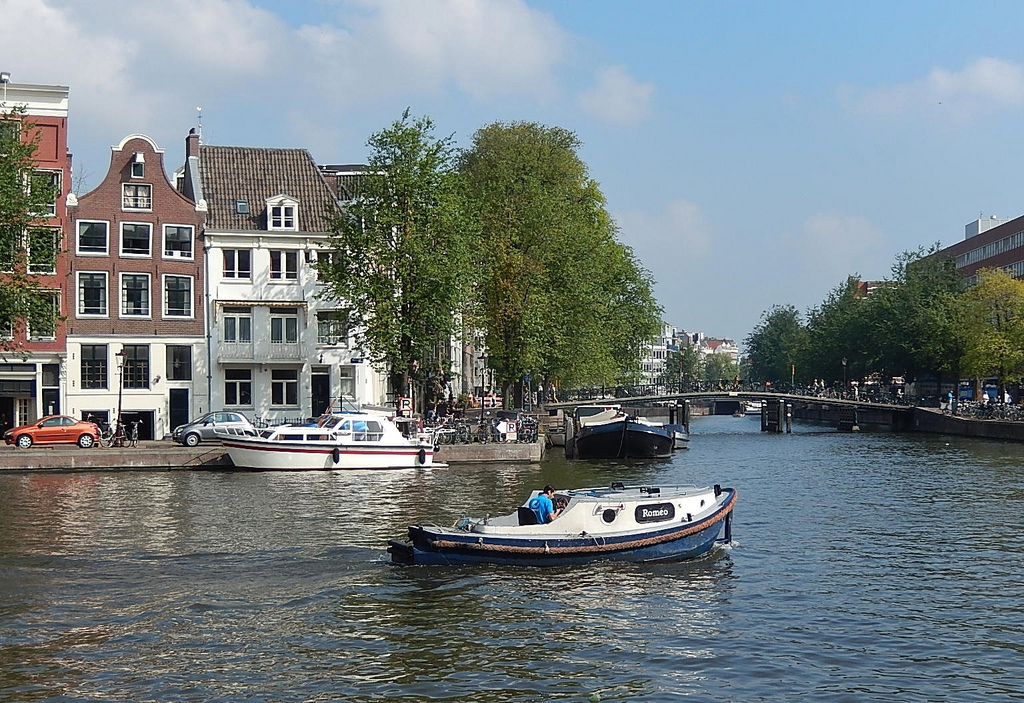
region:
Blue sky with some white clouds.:
[0, 5, 1022, 337]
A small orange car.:
[5, 410, 98, 446]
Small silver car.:
[171, 408, 258, 444]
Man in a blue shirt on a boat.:
[526, 484, 558, 522]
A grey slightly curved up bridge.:
[542, 386, 915, 435]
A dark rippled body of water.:
[0, 409, 1022, 700]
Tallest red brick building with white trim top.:
[0, 73, 77, 431]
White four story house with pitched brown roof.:
[184, 128, 391, 430]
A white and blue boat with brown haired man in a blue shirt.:
[389, 481, 737, 568]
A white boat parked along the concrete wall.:
[207, 409, 438, 470]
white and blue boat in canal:
[399, 458, 805, 579]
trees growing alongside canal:
[399, 123, 703, 441]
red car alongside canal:
[11, 386, 103, 457]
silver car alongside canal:
[176, 403, 268, 451]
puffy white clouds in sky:
[17, 4, 597, 151]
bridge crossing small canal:
[592, 393, 913, 442]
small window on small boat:
[627, 490, 684, 520]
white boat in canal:
[365, 473, 739, 592]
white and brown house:
[87, 124, 347, 486]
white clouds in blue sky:
[845, 81, 941, 139]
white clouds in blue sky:
[710, 227, 750, 244]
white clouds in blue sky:
[646, 63, 736, 168]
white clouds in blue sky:
[485, 37, 552, 83]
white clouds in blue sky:
[342, 28, 423, 92]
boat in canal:
[376, 438, 732, 590]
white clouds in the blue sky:
[98, 6, 197, 68]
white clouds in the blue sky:
[149, 37, 214, 82]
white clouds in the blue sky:
[59, 28, 142, 64]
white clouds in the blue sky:
[444, 24, 518, 50]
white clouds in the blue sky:
[645, 77, 706, 139]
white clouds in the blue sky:
[724, 131, 838, 243]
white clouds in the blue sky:
[618, 151, 670, 208]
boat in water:
[371, 464, 771, 575]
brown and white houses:
[35, 107, 383, 440]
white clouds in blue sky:
[58, 40, 128, 72]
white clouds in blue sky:
[149, 28, 216, 54]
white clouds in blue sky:
[117, 98, 184, 124]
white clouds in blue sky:
[239, 37, 323, 104]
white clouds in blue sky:
[781, 78, 865, 136]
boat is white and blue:
[392, 467, 740, 579]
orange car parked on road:
[3, 411, 106, 456]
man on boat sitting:
[528, 476, 564, 533]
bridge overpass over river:
[528, 372, 934, 449]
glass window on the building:
[74, 218, 106, 251]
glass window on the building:
[118, 219, 150, 252]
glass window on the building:
[160, 223, 190, 250]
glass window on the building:
[70, 273, 106, 313]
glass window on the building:
[115, 273, 151, 316]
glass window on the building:
[157, 273, 189, 315]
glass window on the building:
[78, 337, 107, 383]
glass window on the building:
[118, 343, 145, 382]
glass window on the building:
[163, 337, 189, 375]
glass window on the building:
[217, 246, 234, 270]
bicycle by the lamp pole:
[88, 411, 152, 455]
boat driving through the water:
[377, 456, 753, 585]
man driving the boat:
[522, 471, 575, 547]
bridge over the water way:
[542, 367, 973, 454]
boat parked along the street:
[204, 387, 463, 482]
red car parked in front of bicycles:
[9, 406, 110, 455]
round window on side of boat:
[595, 500, 627, 526]